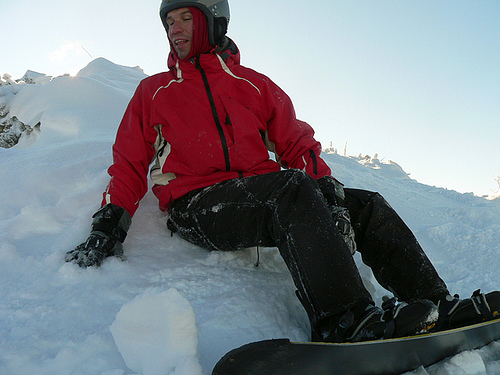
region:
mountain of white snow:
[46, 56, 98, 165]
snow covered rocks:
[6, 102, 49, 179]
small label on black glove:
[79, 231, 109, 254]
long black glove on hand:
[48, 208, 148, 283]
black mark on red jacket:
[209, 100, 250, 140]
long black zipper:
[198, 64, 250, 190]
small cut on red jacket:
[142, 123, 190, 197]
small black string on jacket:
[226, 194, 286, 288]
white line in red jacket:
[216, 54, 266, 95]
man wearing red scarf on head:
[153, 7, 246, 70]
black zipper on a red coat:
[198, 62, 219, 122]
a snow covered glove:
[66, 211, 133, 272]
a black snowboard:
[239, 326, 494, 369]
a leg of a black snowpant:
[279, 179, 344, 317]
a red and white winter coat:
[137, 74, 317, 164]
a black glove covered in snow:
[327, 172, 359, 254]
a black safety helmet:
[209, 4, 231, 47]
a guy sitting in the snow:
[142, 12, 324, 289]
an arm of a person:
[96, 113, 148, 231]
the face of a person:
[162, 11, 194, 54]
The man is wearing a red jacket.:
[76, 58, 367, 216]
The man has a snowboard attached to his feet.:
[190, 295, 497, 372]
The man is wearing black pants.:
[162, 165, 452, 316]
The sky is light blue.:
[308, 23, 498, 108]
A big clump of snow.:
[95, 286, 205, 372]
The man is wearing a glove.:
[55, 190, 152, 295]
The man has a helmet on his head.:
[146, 0, 262, 60]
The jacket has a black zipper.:
[188, 60, 243, 185]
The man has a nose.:
[167, 15, 183, 41]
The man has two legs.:
[177, 172, 459, 335]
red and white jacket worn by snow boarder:
[127, 80, 276, 148]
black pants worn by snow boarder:
[236, 182, 393, 277]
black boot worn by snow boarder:
[322, 301, 423, 333]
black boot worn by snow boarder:
[428, 290, 485, 320]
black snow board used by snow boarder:
[222, 335, 496, 363]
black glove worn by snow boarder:
[88, 212, 125, 258]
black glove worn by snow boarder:
[317, 180, 361, 246]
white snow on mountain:
[19, 278, 226, 353]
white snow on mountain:
[49, 95, 89, 201]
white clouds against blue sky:
[301, 19, 491, 122]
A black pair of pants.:
[196, 146, 433, 351]